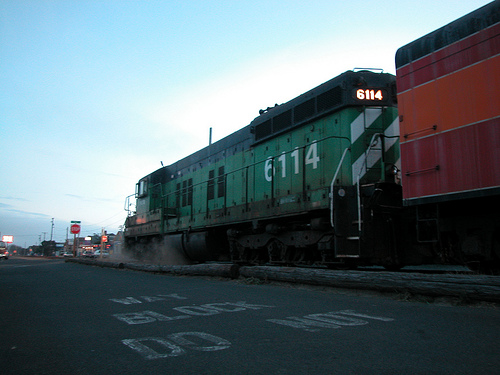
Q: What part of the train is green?
A: The engine.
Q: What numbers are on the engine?
A: 6114.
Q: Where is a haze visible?
A: Front wheels of engine.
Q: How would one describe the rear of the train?
A: Green and white stripes.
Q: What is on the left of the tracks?
A: A sign.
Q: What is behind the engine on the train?
A: Pink, orange and black train car.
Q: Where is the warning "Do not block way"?
A: On the ground.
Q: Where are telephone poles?
A: Along side of tracks.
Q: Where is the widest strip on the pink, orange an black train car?
A: Bottom of car.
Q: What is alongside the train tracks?
A: Wood logs.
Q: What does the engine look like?
A: Green, black and white.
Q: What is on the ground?
A: White letters.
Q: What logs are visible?
A: Wood logs.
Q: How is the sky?
A: Light blue.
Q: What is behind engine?
A: A red and orange train car.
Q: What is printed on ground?
A: Large words on the road that say DO NOT BLOCK WAY.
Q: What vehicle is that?
A: A green train car.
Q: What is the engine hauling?
A: Red, orange and black train car.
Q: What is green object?
A: Train.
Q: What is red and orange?
A: Container.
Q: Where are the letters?
A: On road.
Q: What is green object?
A: Train.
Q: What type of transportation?
A: Train.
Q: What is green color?
A: The Train.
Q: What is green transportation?
A: Train.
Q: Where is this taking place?
A: Near a train track.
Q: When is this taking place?
A: Sometime in the evening.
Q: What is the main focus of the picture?
A: A train.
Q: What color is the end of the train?
A: Green.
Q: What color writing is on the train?
A: White.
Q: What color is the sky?
A: Blue.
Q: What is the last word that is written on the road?
A: Not.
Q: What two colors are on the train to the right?
A: Orange and red.